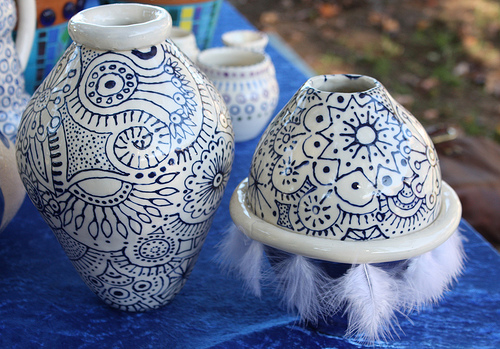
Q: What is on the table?
A: Pottery.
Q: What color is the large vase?
A: Blue and white.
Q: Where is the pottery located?
A: On a table.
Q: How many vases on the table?
A: Two.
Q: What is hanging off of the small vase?
A: Feathers.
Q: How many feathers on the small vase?
A: Six.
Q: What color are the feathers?
A: White.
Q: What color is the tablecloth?
A: Blue.